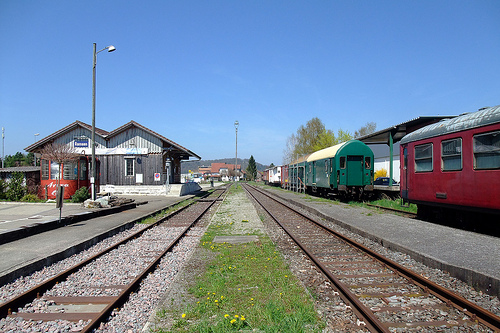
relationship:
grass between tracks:
[156, 179, 315, 332] [237, 179, 487, 332]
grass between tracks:
[156, 179, 315, 332] [1, 183, 230, 331]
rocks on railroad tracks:
[0, 217, 203, 332] [1, 183, 230, 331]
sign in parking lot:
[50, 183, 69, 217] [1, 201, 88, 240]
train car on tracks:
[287, 141, 387, 206] [323, 186, 422, 218]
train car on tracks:
[393, 106, 498, 227] [323, 186, 422, 218]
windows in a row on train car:
[411, 130, 497, 176] [393, 106, 498, 227]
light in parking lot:
[89, 36, 121, 206] [1, 201, 88, 240]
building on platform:
[30, 117, 202, 179] [32, 157, 222, 197]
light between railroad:
[230, 119, 245, 196] [9, 144, 498, 332]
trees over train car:
[278, 113, 370, 150] [287, 141, 387, 206]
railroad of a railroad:
[9, 144, 498, 332] [9, 144, 498, 332]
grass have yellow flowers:
[168, 235, 322, 331] [223, 312, 250, 327]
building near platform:
[30, 117, 202, 179] [32, 157, 222, 197]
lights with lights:
[0, 127, 6, 168] [0, 127, 11, 144]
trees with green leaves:
[281, 117, 337, 166] [312, 135, 325, 144]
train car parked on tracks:
[287, 141, 387, 206] [323, 186, 422, 218]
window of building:
[123, 157, 138, 180] [30, 117, 202, 179]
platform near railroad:
[32, 157, 222, 197] [9, 144, 498, 332]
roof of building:
[23, 117, 200, 153] [30, 117, 202, 179]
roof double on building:
[23, 117, 200, 153] [30, 117, 202, 179]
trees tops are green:
[281, 117, 337, 166] [301, 132, 312, 138]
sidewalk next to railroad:
[1, 195, 184, 300] [9, 144, 498, 332]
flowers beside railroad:
[223, 312, 250, 327] [9, 144, 498, 332]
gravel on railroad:
[90, 258, 140, 278] [9, 144, 498, 332]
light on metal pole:
[89, 36, 121, 206] [91, 41, 98, 203]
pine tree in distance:
[240, 155, 260, 182] [197, 156, 276, 186]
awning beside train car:
[348, 115, 450, 145] [287, 141, 387, 206]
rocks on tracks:
[0, 217, 203, 332] [1, 183, 230, 331]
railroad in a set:
[9, 144, 498, 332] [105, 218, 458, 318]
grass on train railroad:
[156, 179, 315, 332] [9, 144, 498, 332]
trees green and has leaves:
[281, 117, 337, 166] [312, 135, 325, 144]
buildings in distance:
[201, 162, 244, 185] [197, 156, 276, 186]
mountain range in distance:
[185, 155, 270, 174] [197, 156, 276, 186]